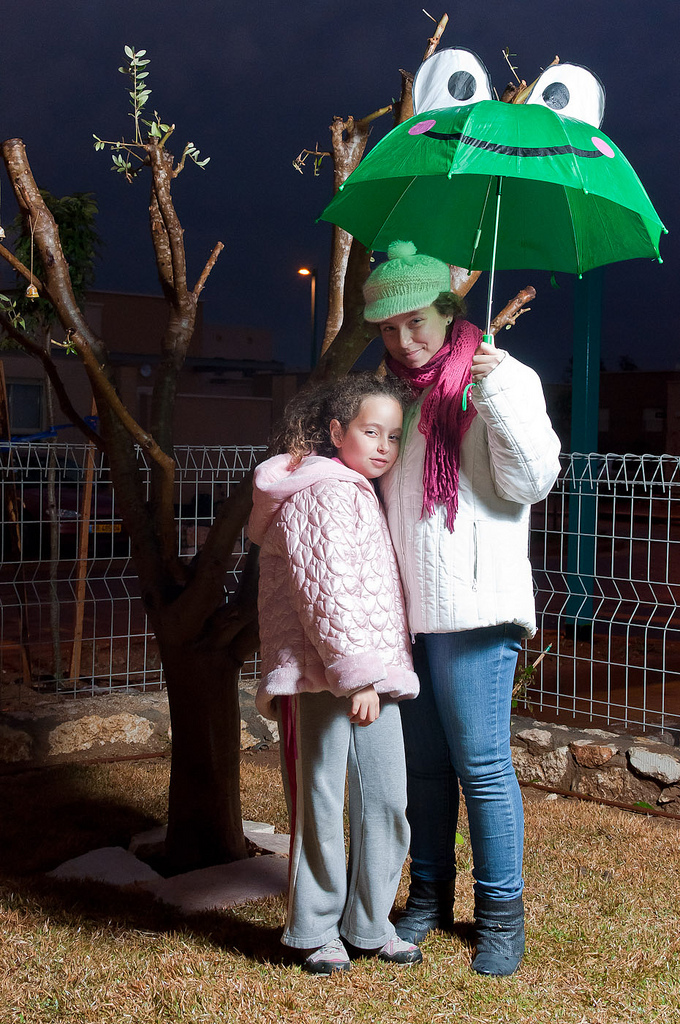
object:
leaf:
[124, 46, 134, 60]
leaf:
[135, 49, 146, 56]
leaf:
[135, 59, 151, 66]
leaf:
[135, 72, 148, 79]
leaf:
[136, 84, 146, 88]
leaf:
[136, 90, 152, 99]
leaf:
[93, 134, 102, 142]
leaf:
[112, 154, 123, 167]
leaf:
[196, 157, 210, 166]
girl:
[248, 371, 423, 974]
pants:
[273, 693, 411, 949]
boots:
[471, 896, 524, 976]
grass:
[102, 912, 251, 1015]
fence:
[509, 452, 680, 737]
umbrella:
[310, 47, 668, 412]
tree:
[0, 9, 558, 862]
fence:
[0, 433, 678, 737]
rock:
[0, 681, 679, 820]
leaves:
[92, 45, 210, 173]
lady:
[362, 236, 562, 976]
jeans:
[397, 623, 523, 902]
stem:
[134, 58, 139, 144]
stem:
[99, 140, 145, 145]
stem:
[173, 143, 190, 178]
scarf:
[383, 313, 485, 536]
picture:
[0, 0, 680, 1024]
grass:
[532, 821, 657, 1017]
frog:
[405, 46, 612, 164]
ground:
[0, 528, 678, 1021]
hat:
[363, 240, 450, 323]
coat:
[245, 452, 419, 721]